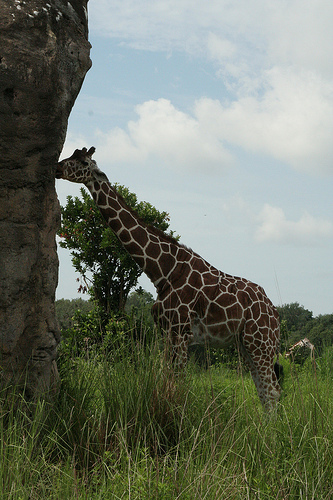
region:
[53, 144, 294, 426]
a giraffe standing by a rock wall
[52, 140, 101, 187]
the head of a giraffe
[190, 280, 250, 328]
the spots on the coat of a giraffe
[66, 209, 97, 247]
the leaves of a tree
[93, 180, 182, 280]
the neck of a giraffe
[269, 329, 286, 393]
the tail of a giraffe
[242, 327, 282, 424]
the hind leg of a giraffe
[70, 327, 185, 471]
the blades of tall grass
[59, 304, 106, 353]
the leaves a bush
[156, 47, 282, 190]
the clouds in the sky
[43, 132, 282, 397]
Giraffe standing in the field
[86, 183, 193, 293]
Giraffe with a long neck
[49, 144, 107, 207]
Giraffe eating from a tree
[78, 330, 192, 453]
Grass in the field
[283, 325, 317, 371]
Tree stump in the field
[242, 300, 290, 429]
Giraffe with long legs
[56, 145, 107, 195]
Giraffe with it head up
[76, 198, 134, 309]
Tree behind a giraffe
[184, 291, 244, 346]
Giraffe with a big belly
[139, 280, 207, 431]
Giraffe with long legs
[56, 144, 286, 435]
a giraffe facing gray rock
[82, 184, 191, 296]
a giraffe with long neck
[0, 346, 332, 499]
giraffe standing in green grass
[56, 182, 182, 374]
green trees on right of giraffe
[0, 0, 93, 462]
a tall gray rock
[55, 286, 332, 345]
bunch of green trees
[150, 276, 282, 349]
short body of a giraffe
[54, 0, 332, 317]
a bright sunny day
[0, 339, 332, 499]
mixed of weed and grass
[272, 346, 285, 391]
short black tail of the giraffe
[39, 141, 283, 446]
giraffe finds something in rock wall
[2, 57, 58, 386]
moisture seeping through the rock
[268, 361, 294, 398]
swatch of black hair on tail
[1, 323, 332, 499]
high green grass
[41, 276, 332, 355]
trees and brush farther away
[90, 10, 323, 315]
sky looks hazy in the distance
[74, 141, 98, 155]
horns on giraffe head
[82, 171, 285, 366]
giraffe coat is patterned like a mosaic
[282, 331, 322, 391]
a worn piece of wood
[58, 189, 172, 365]
one tree grows closer to cliff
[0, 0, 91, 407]
a giant rock in front of a giraffe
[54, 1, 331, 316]
a blue and white cloudy sky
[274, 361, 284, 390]
black hair at the end of a giraffe tail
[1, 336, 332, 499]
tall grass around a giraffe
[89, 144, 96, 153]
a horn on a giraffe's head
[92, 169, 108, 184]
a giraffe ear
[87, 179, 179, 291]
a long giraffe neck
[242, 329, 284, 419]
a long giraffe hind leg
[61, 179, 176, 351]
a tree behind a giraffe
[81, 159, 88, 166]
the eye of a giraffe